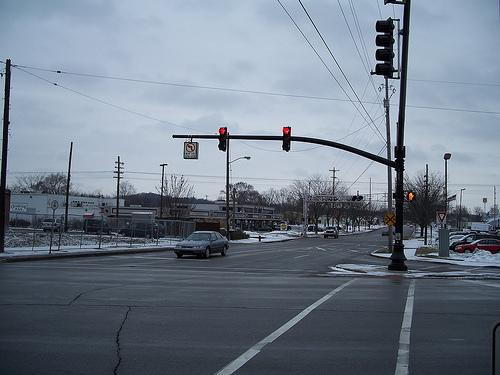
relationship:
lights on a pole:
[372, 16, 399, 82] [384, 0, 411, 272]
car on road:
[170, 227, 231, 260] [0, 219, 484, 373]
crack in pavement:
[109, 300, 133, 372] [0, 220, 484, 372]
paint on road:
[206, 274, 417, 373] [0, 219, 484, 373]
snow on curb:
[451, 247, 484, 261] [370, 234, 484, 270]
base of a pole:
[384, 239, 409, 273] [381, 0, 412, 272]